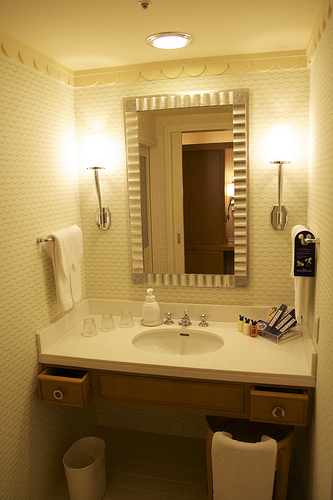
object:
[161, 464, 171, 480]
tile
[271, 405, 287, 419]
handle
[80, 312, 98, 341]
cups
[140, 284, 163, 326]
dispenser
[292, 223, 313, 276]
hanger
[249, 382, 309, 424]
drawer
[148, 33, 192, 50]
ceiling light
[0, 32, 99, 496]
wall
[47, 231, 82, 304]
towel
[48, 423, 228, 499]
floor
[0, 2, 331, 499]
building